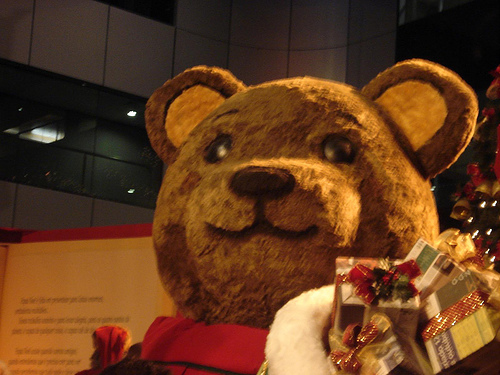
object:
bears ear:
[360, 59, 479, 179]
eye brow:
[211, 109, 239, 124]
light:
[128, 188, 136, 193]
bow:
[348, 260, 422, 305]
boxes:
[327, 313, 407, 375]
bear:
[100, 58, 497, 375]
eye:
[204, 134, 232, 163]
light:
[7, 124, 67, 144]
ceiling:
[2, 60, 148, 132]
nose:
[229, 165, 296, 199]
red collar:
[141, 316, 271, 375]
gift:
[402, 238, 467, 293]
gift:
[418, 289, 497, 374]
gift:
[327, 313, 404, 374]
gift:
[419, 269, 476, 321]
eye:
[322, 134, 356, 164]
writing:
[18, 296, 104, 303]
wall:
[0, 236, 109, 358]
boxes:
[331, 256, 420, 351]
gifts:
[434, 228, 500, 342]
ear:
[144, 65, 247, 166]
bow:
[331, 322, 381, 373]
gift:
[333, 256, 420, 343]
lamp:
[127, 111, 137, 117]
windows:
[0, 59, 163, 207]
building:
[0, 0, 403, 230]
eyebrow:
[335, 109, 362, 127]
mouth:
[204, 202, 318, 241]